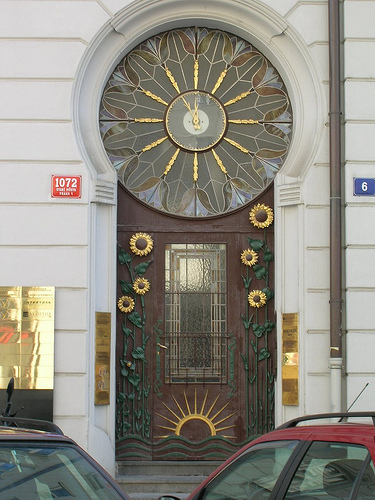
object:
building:
[0, 0, 374, 498]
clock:
[98, 25, 294, 219]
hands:
[179, 91, 203, 129]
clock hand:
[181, 93, 197, 123]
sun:
[135, 60, 260, 180]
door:
[114, 181, 274, 464]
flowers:
[239, 244, 270, 324]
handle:
[154, 340, 168, 352]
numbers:
[54, 178, 79, 189]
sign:
[353, 178, 374, 196]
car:
[158, 410, 374, 497]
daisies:
[128, 231, 153, 259]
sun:
[149, 386, 242, 443]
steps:
[113, 460, 276, 496]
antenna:
[333, 381, 370, 426]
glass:
[162, 242, 230, 386]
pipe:
[328, 0, 342, 413]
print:
[53, 178, 78, 197]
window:
[96, 18, 298, 220]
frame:
[83, 179, 308, 485]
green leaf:
[247, 326, 277, 399]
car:
[0, 419, 134, 498]